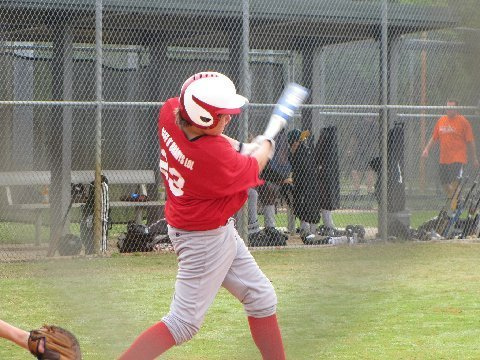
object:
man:
[87, 64, 311, 357]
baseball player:
[93, 52, 328, 359]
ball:
[463, 203, 479, 210]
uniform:
[145, 96, 269, 233]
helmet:
[161, 58, 249, 133]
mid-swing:
[237, 58, 339, 200]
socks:
[245, 311, 291, 360]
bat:
[253, 70, 318, 145]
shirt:
[419, 105, 476, 168]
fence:
[0, 0, 480, 238]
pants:
[138, 221, 291, 345]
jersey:
[149, 96, 267, 231]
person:
[0, 309, 86, 360]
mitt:
[19, 319, 92, 358]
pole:
[90, 0, 110, 268]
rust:
[91, 8, 106, 101]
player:
[86, 51, 311, 360]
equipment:
[296, 172, 480, 244]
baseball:
[298, 221, 365, 250]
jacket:
[284, 150, 326, 224]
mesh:
[2, 31, 157, 76]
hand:
[26, 315, 76, 354]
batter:
[116, 59, 316, 360]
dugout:
[0, 0, 473, 74]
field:
[291, 233, 479, 360]